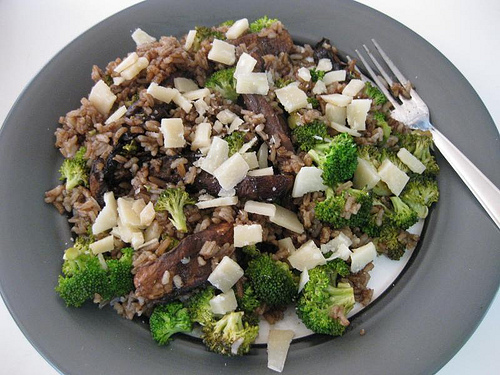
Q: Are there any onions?
A: Yes, there is an onion.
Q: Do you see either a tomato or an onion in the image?
A: Yes, there is an onion.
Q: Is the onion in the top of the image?
A: No, the onion is in the bottom of the image.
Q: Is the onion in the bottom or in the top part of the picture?
A: The onion is in the bottom of the image.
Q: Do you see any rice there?
A: Yes, there is rice.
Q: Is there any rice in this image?
A: Yes, there is rice.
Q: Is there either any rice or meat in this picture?
A: Yes, there is rice.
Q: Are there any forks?
A: Yes, there is a fork.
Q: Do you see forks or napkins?
A: Yes, there is a fork.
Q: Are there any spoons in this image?
A: No, there are no spoons.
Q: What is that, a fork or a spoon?
A: That is a fork.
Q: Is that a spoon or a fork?
A: That is a fork.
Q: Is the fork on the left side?
A: No, the fork is on the right of the image.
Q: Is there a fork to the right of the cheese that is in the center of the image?
A: Yes, there is a fork to the right of the cheese.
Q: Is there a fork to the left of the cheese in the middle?
A: No, the fork is to the right of the cheese.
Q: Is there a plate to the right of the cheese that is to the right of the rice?
A: No, there is a fork to the right of the cheese.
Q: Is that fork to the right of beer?
A: No, the fork is to the right of the cheese.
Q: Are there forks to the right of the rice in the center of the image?
A: Yes, there is a fork to the right of the rice.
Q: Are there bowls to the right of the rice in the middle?
A: No, there is a fork to the right of the rice.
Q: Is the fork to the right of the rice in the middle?
A: Yes, the fork is to the right of the rice.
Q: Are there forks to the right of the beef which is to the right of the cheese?
A: Yes, there is a fork to the right of the beef.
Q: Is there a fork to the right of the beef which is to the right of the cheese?
A: Yes, there is a fork to the right of the beef.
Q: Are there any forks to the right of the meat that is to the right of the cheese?
A: Yes, there is a fork to the right of the beef.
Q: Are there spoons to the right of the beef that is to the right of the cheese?
A: No, there is a fork to the right of the beef.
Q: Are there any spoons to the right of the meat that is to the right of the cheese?
A: No, there is a fork to the right of the beef.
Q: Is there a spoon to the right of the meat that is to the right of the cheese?
A: No, there is a fork to the right of the beef.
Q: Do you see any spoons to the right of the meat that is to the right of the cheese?
A: No, there is a fork to the right of the beef.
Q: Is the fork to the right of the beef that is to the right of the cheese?
A: Yes, the fork is to the right of the beef.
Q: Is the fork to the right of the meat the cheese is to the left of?
A: Yes, the fork is to the right of the beef.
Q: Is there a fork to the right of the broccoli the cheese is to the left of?
A: Yes, there is a fork to the right of the broccoli.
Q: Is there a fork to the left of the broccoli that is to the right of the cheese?
A: No, the fork is to the right of the broccoli.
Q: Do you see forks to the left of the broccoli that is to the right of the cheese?
A: No, the fork is to the right of the broccoli.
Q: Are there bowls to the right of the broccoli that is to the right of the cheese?
A: No, there is a fork to the right of the broccoli.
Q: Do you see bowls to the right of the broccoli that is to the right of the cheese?
A: No, there is a fork to the right of the broccoli.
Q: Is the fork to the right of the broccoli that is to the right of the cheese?
A: Yes, the fork is to the right of the broccoli.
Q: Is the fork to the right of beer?
A: No, the fork is to the right of the broccoli.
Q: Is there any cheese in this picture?
A: Yes, there is cheese.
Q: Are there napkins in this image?
A: No, there are no napkins.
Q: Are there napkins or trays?
A: No, there are no napkins or trays.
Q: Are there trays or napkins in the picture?
A: No, there are no napkins or trays.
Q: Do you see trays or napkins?
A: No, there are no napkins or trays.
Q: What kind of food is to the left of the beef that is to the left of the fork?
A: The food is cheese.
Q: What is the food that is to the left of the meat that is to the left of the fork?
A: The food is cheese.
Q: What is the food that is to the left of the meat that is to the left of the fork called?
A: The food is cheese.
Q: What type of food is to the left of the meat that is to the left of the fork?
A: The food is cheese.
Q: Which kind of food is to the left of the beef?
A: The food is cheese.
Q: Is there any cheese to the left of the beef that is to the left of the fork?
A: Yes, there is cheese to the left of the beef.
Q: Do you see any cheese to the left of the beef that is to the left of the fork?
A: Yes, there is cheese to the left of the beef.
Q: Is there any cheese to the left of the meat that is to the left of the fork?
A: Yes, there is cheese to the left of the beef.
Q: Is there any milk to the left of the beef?
A: No, there is cheese to the left of the beef.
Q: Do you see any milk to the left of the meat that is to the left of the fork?
A: No, there is cheese to the left of the beef.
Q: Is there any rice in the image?
A: Yes, there is rice.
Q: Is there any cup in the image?
A: No, there are no cups.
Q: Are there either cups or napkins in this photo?
A: No, there are no cups or napkins.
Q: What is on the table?
A: The rice is on the table.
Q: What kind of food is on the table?
A: The food is rice.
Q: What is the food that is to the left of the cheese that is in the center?
A: The food is rice.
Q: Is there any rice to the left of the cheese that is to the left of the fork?
A: Yes, there is rice to the left of the cheese.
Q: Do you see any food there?
A: Yes, there is food.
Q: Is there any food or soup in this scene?
A: Yes, there is food.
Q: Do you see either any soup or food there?
A: Yes, there is food.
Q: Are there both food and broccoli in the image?
A: Yes, there are both food and broccoli.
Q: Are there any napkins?
A: No, there are no napkins.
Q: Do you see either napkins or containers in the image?
A: No, there are no napkins or containers.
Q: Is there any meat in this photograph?
A: Yes, there is meat.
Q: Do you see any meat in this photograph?
A: Yes, there is meat.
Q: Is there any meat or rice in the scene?
A: Yes, there is meat.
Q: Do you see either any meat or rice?
A: Yes, there is meat.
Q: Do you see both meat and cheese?
A: Yes, there are both meat and cheese.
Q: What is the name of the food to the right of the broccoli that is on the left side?
A: The food is meat.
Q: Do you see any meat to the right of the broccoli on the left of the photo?
A: Yes, there is meat to the right of the broccoli.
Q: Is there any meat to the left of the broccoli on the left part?
A: No, the meat is to the right of the broccoli.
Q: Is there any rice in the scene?
A: Yes, there is rice.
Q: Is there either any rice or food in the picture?
A: Yes, there is rice.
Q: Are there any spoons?
A: No, there are no spoons.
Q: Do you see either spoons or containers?
A: No, there are no spoons or containers.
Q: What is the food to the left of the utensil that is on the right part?
A: The food is rice.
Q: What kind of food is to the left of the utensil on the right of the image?
A: The food is rice.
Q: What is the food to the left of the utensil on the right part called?
A: The food is rice.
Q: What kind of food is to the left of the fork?
A: The food is rice.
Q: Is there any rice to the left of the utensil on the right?
A: Yes, there is rice to the left of the fork.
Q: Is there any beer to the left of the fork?
A: No, there is rice to the left of the fork.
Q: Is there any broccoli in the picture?
A: Yes, there is broccoli.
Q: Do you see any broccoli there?
A: Yes, there is broccoli.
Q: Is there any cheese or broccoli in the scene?
A: Yes, there is broccoli.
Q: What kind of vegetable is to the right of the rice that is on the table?
A: The vegetable is broccoli.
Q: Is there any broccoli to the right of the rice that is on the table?
A: Yes, there is broccoli to the right of the rice.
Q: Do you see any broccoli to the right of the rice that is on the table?
A: Yes, there is broccoli to the right of the rice.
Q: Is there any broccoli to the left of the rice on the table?
A: No, the broccoli is to the right of the rice.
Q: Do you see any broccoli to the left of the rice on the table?
A: No, the broccoli is to the right of the rice.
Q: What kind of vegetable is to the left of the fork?
A: The vegetable is broccoli.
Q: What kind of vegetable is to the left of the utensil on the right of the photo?
A: The vegetable is broccoli.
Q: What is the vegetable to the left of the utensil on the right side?
A: The vegetable is broccoli.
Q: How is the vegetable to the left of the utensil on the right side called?
A: The vegetable is broccoli.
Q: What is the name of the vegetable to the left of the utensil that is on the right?
A: The vegetable is broccoli.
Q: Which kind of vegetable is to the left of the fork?
A: The vegetable is broccoli.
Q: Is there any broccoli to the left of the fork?
A: Yes, there is broccoli to the left of the fork.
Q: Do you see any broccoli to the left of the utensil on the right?
A: Yes, there is broccoli to the left of the fork.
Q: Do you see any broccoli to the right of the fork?
A: No, the broccoli is to the left of the fork.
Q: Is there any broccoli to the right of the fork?
A: No, the broccoli is to the left of the fork.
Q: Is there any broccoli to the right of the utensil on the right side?
A: No, the broccoli is to the left of the fork.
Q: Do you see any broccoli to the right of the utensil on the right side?
A: No, the broccoli is to the left of the fork.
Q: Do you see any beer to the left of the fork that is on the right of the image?
A: No, there is broccoli to the left of the fork.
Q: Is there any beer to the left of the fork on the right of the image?
A: No, there is broccoli to the left of the fork.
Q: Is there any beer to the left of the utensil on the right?
A: No, there is broccoli to the left of the fork.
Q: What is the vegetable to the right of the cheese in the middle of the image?
A: The vegetable is broccoli.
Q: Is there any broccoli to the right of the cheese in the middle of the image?
A: Yes, there is broccoli to the right of the cheese.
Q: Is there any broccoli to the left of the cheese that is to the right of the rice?
A: No, the broccoli is to the right of the cheese.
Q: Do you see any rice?
A: Yes, there is rice.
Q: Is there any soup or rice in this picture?
A: Yes, there is rice.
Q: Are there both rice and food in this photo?
A: Yes, there are both rice and food.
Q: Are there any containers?
A: No, there are no containers.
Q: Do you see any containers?
A: No, there are no containers.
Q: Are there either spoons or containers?
A: No, there are no containers or spoons.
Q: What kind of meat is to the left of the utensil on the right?
A: The meat is beef.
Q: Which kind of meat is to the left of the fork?
A: The meat is beef.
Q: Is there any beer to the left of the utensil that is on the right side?
A: No, there is beef to the left of the fork.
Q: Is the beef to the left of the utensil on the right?
A: Yes, the beef is to the left of the fork.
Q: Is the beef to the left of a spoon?
A: No, the beef is to the left of the fork.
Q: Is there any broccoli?
A: Yes, there is broccoli.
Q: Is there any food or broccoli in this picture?
A: Yes, there is broccoli.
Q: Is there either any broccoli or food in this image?
A: Yes, there is broccoli.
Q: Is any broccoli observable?
A: Yes, there is broccoli.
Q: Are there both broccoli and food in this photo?
A: Yes, there are both broccoli and food.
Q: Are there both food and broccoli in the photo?
A: Yes, there are both broccoli and food.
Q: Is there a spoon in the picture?
A: No, there are no spoons.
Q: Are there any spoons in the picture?
A: No, there are no spoons.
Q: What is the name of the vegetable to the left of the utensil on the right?
A: The vegetable is broccoli.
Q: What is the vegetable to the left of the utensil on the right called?
A: The vegetable is broccoli.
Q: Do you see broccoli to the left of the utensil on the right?
A: Yes, there is broccoli to the left of the fork.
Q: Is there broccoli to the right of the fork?
A: No, the broccoli is to the left of the fork.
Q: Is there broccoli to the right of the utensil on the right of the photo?
A: No, the broccoli is to the left of the fork.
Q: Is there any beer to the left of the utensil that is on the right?
A: No, there is broccoli to the left of the fork.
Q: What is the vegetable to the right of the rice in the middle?
A: The vegetable is broccoli.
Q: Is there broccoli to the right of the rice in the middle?
A: Yes, there is broccoli to the right of the rice.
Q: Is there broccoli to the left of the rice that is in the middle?
A: No, the broccoli is to the right of the rice.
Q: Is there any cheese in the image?
A: Yes, there is cheese.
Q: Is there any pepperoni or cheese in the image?
A: Yes, there is cheese.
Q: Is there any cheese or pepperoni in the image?
A: Yes, there is cheese.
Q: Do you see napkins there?
A: No, there are no napkins.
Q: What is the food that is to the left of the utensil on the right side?
A: The food is cheese.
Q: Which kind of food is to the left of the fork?
A: The food is cheese.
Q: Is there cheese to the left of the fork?
A: Yes, there is cheese to the left of the fork.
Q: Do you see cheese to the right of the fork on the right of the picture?
A: No, the cheese is to the left of the fork.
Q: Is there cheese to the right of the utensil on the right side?
A: No, the cheese is to the left of the fork.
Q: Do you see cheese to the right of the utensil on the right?
A: No, the cheese is to the left of the fork.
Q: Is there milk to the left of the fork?
A: No, there is cheese to the left of the fork.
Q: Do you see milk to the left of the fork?
A: No, there is cheese to the left of the fork.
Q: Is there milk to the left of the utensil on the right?
A: No, there is cheese to the left of the fork.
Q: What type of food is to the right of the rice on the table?
A: The food is cheese.